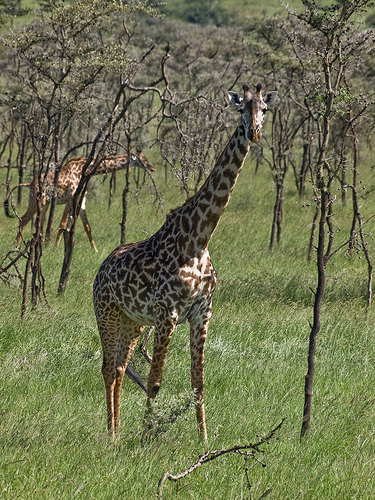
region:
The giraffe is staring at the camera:
[92, 82, 278, 449]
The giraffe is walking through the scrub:
[2, 150, 155, 252]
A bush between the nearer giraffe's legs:
[142, 386, 202, 441]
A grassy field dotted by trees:
[0, 0, 374, 499]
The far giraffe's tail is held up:
[4, 181, 31, 218]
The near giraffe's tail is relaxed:
[125, 363, 149, 395]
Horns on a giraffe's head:
[241, 79, 262, 96]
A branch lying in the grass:
[139, 414, 283, 498]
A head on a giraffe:
[220, 79, 277, 143]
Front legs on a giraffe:
[145, 304, 207, 444]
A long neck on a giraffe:
[186, 118, 246, 259]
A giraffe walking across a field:
[13, 150, 154, 248]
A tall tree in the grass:
[4, 2, 144, 321]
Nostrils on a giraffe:
[248, 122, 261, 132]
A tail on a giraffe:
[4, 182, 27, 197]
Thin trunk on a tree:
[299, 105, 327, 441]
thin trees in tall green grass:
[1, 1, 374, 499]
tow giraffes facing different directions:
[4, 82, 278, 445]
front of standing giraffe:
[93, 84, 277, 441]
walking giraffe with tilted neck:
[4, 149, 154, 255]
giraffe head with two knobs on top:
[229, 84, 278, 142]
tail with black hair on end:
[3, 182, 29, 218]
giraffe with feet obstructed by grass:
[14, 149, 154, 260]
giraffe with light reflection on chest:
[93, 81, 276, 445]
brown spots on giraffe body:
[92, 84, 277, 445]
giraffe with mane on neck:
[4, 147, 154, 252]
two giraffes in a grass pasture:
[25, 69, 296, 444]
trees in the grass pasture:
[3, 1, 370, 498]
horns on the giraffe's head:
[241, 79, 261, 92]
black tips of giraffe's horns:
[242, 79, 261, 91]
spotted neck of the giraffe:
[190, 120, 248, 238]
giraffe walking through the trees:
[3, 149, 153, 255]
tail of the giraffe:
[0, 172, 28, 213]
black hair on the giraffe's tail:
[1, 197, 15, 218]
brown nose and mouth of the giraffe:
[248, 127, 260, 139]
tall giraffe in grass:
[106, 104, 275, 418]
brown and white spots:
[105, 138, 233, 333]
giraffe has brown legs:
[94, 336, 209, 427]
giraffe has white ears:
[220, 87, 275, 118]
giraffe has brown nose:
[244, 122, 263, 146]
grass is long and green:
[236, 308, 311, 437]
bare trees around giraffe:
[78, 44, 338, 174]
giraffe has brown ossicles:
[239, 74, 275, 112]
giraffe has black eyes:
[239, 99, 269, 113]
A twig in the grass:
[156, 415, 286, 498]